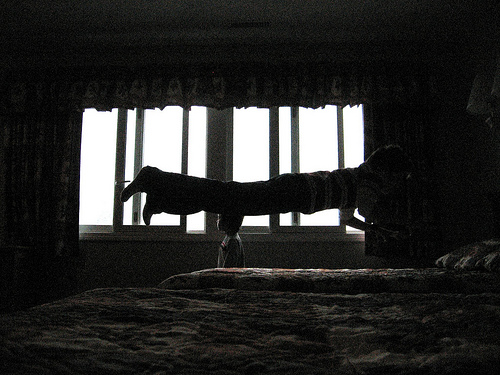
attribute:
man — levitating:
[109, 138, 420, 241]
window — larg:
[86, 111, 359, 169]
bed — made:
[31, 291, 493, 368]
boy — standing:
[218, 217, 248, 264]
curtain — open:
[5, 118, 73, 294]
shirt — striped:
[307, 172, 373, 209]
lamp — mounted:
[462, 76, 499, 126]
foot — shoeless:
[120, 167, 144, 205]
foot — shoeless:
[140, 203, 155, 227]